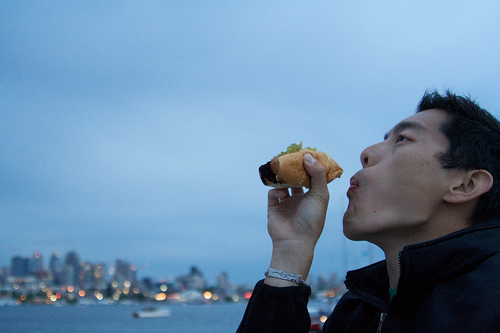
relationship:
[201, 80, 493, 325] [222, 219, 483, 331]
man in jacket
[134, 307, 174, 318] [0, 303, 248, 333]
boat in river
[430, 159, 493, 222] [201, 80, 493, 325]
ear on man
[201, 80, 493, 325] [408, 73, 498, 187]
man has hair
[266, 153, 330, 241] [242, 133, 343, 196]
hand holding sandwich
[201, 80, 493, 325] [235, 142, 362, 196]
man eating dog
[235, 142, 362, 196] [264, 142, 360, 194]
dog in bun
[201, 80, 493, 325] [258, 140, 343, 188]
man eating bun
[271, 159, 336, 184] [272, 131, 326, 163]
dog with lettuce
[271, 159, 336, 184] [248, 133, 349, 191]
dog in bun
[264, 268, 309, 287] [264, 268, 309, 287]
bracelet on bracelet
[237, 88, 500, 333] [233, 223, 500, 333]
man wearing jacket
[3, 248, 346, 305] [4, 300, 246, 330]
buildings on river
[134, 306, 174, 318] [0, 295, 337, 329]
boat on river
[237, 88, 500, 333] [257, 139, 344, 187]
man holding sandwich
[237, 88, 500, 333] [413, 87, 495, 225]
man with hair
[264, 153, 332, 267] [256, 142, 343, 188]
hand holding sandwich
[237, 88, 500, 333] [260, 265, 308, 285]
man wearing bracelet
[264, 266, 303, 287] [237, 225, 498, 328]
bracelet next to jacket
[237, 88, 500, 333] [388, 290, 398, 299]
man wearing shirt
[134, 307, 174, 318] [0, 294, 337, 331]
boat in water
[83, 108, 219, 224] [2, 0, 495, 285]
clouds in sky